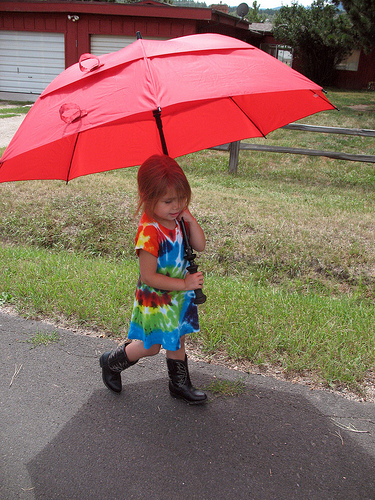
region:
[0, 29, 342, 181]
The umbrella is red.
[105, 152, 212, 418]
The girl is wearing boots.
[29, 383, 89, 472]
This asphalt is grey.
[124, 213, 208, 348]
The dress is tie dyed.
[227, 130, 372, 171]
The fence is wood.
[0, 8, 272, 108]
The garage is red.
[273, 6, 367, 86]
The tree is green.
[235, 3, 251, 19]
There is a satellite dish on the roof.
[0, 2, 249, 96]
red garage with two doors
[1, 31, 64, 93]
surface of closed white door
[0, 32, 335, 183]
top of open red umbrella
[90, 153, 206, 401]
girl in tie dye dress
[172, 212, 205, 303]
two hands on umbrella pole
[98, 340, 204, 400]
cowboy boots on feet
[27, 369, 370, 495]
umbrella shadow on paved surface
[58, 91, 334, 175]
wire poles of umbrella frame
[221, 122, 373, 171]
wood posts of fence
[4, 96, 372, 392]
dried grass and green grass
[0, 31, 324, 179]
the umbrella is red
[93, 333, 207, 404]
the boots are black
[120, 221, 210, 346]
the dress is colorfull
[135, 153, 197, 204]
her hair is brown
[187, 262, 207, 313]
the handle is black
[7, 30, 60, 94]
the door is white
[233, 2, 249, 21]
dish is on the roof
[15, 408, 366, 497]
the road is grey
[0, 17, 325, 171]
large red umbrella held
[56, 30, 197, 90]
top red cover of umbrella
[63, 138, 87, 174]
black support bar of umbrella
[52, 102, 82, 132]
red loop on top of umbrella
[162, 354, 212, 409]
black shoe on foot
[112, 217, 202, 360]
tie dye dress on girl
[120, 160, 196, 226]
brown hair of young girl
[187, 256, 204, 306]
black bottom of handle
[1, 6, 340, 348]
young girl holding an umbrella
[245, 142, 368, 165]
brown wooden post of fence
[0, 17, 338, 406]
little girl holding umbrella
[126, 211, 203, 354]
little girl's dress is tie die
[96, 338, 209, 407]
little girl's boots are black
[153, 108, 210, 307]
umbrella handle is black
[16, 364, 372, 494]
shadow of umbrella on ground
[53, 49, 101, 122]
straps on umbrella is red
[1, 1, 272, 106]
the building is red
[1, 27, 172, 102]
white doors on building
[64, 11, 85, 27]
light on the building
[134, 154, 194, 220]
girl's hair is blonde